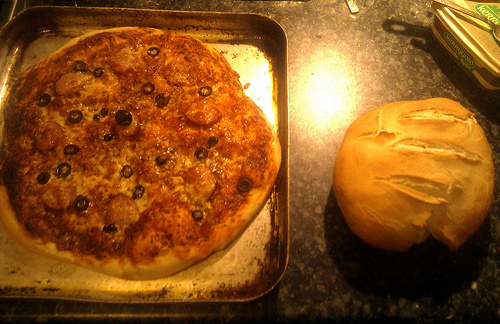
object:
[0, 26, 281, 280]
pizza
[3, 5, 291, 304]
pan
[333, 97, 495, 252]
bread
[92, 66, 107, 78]
olive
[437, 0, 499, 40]
spoon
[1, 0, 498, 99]
counter top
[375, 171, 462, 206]
cut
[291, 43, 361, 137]
light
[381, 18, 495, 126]
shadow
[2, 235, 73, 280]
shadow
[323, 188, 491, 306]
shadow